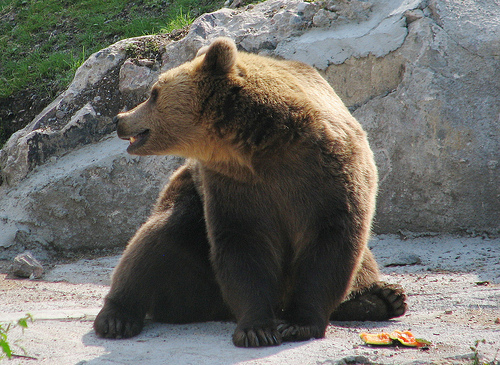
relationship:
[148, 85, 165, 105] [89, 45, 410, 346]
ear of a bear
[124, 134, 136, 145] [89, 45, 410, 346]
tooth of bear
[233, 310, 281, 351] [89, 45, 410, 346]
paw of bear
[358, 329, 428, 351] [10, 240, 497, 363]
food of ground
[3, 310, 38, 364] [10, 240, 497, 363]
green leaves of ground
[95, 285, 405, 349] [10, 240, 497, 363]
paws of ground